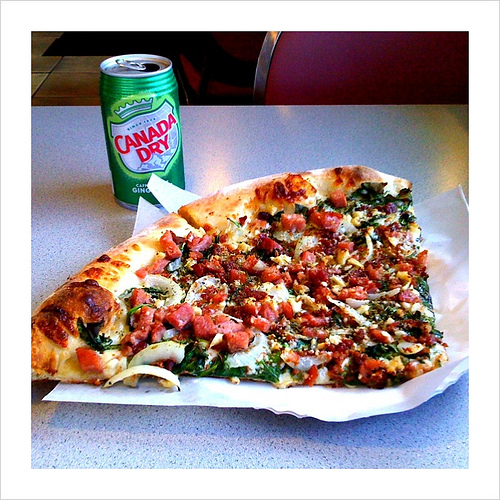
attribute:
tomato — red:
[72, 344, 111, 373]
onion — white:
[112, 332, 197, 390]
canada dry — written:
[109, 114, 182, 163]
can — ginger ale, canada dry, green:
[94, 49, 189, 211]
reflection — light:
[222, 100, 464, 165]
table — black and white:
[238, 111, 483, 171]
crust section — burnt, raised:
[35, 277, 132, 382]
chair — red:
[251, 31, 469, 106]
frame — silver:
[250, 30, 284, 105]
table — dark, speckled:
[59, 392, 458, 493]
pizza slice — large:
[177, 168, 452, 377]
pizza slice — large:
[28, 208, 409, 382]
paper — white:
[35, 170, 475, 430]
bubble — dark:
[57, 276, 117, 330]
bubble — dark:
[258, 169, 314, 212]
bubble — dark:
[330, 163, 383, 202]